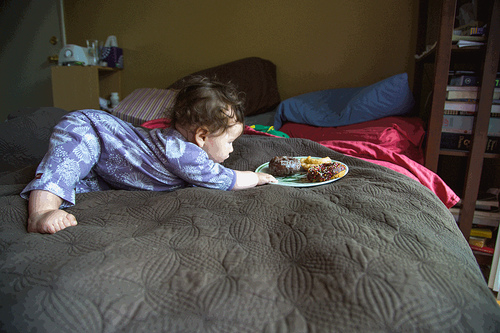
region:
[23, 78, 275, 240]
Baby on the bed.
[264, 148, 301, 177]
Donut on the plate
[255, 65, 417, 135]
Blue pillow on the bed.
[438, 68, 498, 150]
Books in the shelf.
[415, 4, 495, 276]
Bookshelf in the background.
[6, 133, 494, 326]
Gray bedspread on the bed.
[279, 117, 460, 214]
Pink sheet on the bed.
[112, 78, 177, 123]
Striped pillow on the bed.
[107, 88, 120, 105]
Bottle of medicine on the shelf.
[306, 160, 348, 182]
Sprinkles on the donut.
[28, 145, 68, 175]
a babys purple outfit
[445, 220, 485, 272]
a grey blanket on the bed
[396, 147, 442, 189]
pink sheets on the bed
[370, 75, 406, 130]
blue pillow on the bed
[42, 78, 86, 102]
a book case next to the bed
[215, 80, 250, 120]
the babys hair on its head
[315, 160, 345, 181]
a plate of food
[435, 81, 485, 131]
a book shelf n thebed room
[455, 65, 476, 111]
books on the book shelf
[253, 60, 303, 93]
a brown pillow on the bed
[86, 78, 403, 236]
baby reaching out for the plate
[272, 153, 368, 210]
food on the plate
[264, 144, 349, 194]
food on the plate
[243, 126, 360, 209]
food on the plate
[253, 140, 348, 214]
plate on the bed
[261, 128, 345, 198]
plate under the food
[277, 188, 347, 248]
blanket under the plate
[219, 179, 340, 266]
design on the blanket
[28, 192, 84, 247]
foot of the kid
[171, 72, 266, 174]
head of the kid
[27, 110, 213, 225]
outfit on the kid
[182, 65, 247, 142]
hair on the kid's head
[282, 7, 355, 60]
wall in the background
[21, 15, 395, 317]
a baby on a bed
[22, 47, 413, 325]
the baby is laying down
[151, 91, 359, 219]
the baby is reaching for a plate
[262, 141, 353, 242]
the plate has food on it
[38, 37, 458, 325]
picture taken indoors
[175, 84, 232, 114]
the baby has short hair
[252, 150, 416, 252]
the plate is round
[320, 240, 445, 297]
the blanket is gray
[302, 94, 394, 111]
the pillow is blue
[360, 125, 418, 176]
the sheets are pink